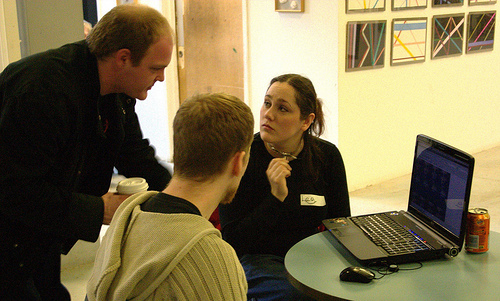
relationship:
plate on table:
[14, 23, 45, 38] [142, 13, 177, 40]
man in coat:
[90, 12, 172, 82] [15, 57, 89, 156]